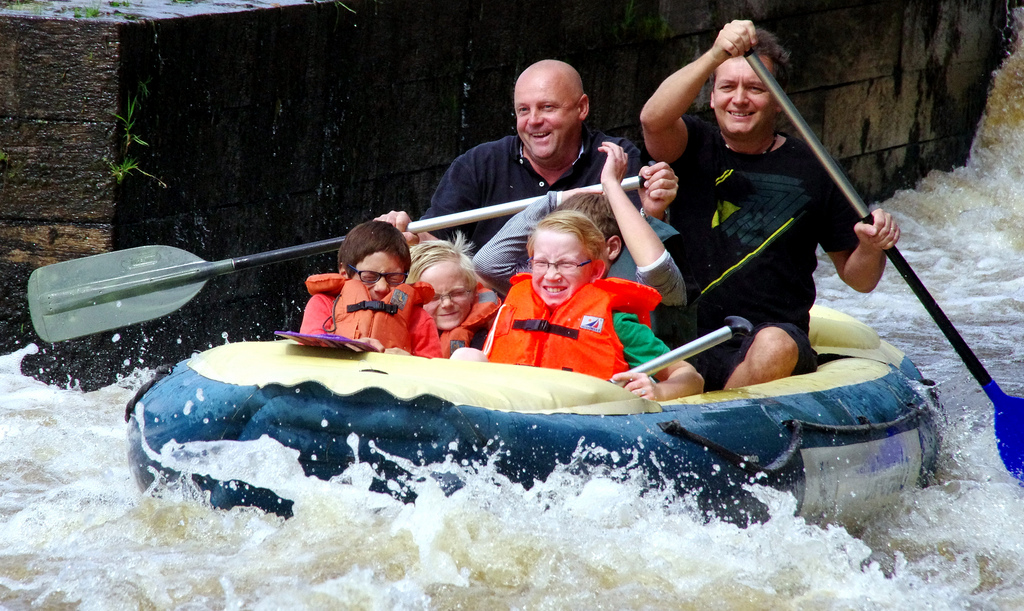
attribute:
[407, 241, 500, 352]
person — sitting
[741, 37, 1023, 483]
paddle — rafting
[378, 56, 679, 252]
person — sitting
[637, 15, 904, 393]
person — sitting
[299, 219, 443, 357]
person — sitting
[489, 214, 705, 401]
person — sitting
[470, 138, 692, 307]
person — sitting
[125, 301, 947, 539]
raft — black , inflatable, blue, white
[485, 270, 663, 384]
vest — orange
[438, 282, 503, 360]
vest — orange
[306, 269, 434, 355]
vest — orange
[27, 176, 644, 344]
paddle — green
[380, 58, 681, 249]
man — bald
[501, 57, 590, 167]
part — human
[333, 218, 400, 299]
part — human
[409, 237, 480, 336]
part — human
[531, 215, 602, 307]
part — human